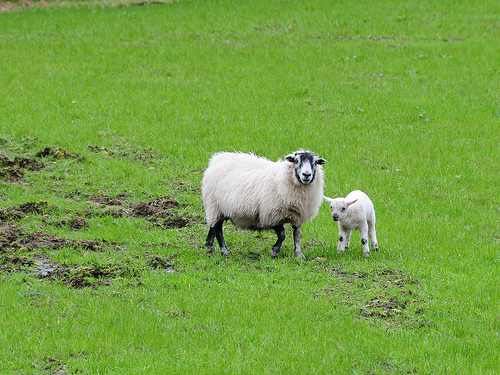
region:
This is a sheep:
[194, 131, 329, 270]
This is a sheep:
[321, 178, 391, 271]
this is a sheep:
[148, 120, 340, 276]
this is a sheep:
[321, 183, 393, 264]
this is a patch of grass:
[147, 294, 254, 365]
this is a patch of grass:
[290, 322, 366, 359]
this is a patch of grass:
[407, 203, 464, 279]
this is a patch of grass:
[134, 80, 198, 154]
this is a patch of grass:
[95, 325, 169, 372]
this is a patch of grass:
[236, 325, 308, 370]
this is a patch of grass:
[354, 93, 427, 168]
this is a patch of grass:
[107, 86, 178, 148]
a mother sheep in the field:
[200, 148, 325, 258]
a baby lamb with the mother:
[321, 190, 376, 255]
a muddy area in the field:
[0, 200, 180, 285]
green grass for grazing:
[0, 0, 496, 145]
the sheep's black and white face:
[285, 150, 325, 185]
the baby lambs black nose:
[332, 212, 339, 222]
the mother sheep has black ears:
[285, 155, 297, 163]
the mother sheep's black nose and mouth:
[301, 171, 313, 182]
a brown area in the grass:
[1, 0, 175, 12]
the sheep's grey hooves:
[269, 246, 280, 257]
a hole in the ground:
[141, 230, 181, 287]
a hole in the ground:
[55, 255, 112, 300]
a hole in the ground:
[7, 219, 62, 279]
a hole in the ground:
[25, 343, 58, 373]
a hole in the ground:
[102, 193, 176, 243]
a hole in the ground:
[150, 208, 198, 246]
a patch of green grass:
[181, 292, 250, 357]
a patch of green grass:
[110, 299, 160, 373]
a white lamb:
[323, 185, 379, 260]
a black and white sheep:
[198, 140, 325, 266]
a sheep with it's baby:
[193, 138, 383, 267]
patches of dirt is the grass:
[2, 128, 198, 303]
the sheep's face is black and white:
[282, 147, 329, 191]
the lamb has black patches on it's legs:
[322, 190, 383, 260]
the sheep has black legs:
[196, 145, 326, 264]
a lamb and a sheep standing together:
[198, 145, 384, 255]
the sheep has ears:
[281, 148, 328, 168]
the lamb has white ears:
[321, 192, 357, 209]